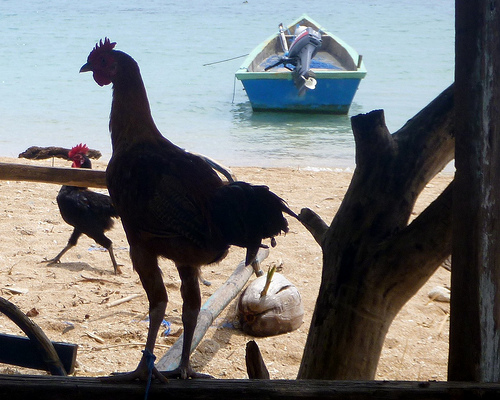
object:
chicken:
[79, 32, 298, 396]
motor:
[285, 28, 319, 91]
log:
[149, 246, 275, 371]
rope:
[204, 52, 249, 67]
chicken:
[40, 144, 124, 278]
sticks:
[104, 289, 141, 309]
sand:
[0, 154, 456, 383]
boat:
[232, 14, 367, 116]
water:
[0, 0, 500, 170]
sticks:
[83, 328, 106, 343]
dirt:
[0, 158, 453, 384]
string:
[139, 349, 157, 397]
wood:
[0, 367, 495, 398]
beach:
[0, 156, 498, 386]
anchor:
[227, 73, 237, 106]